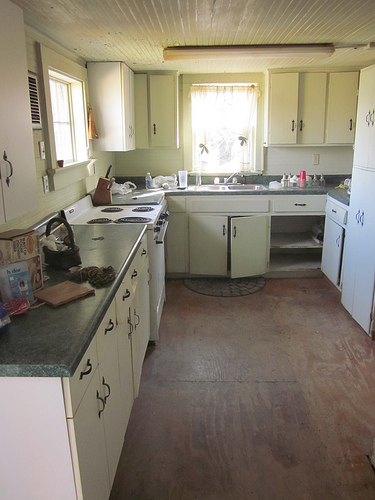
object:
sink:
[190, 172, 267, 192]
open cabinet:
[231, 213, 269, 280]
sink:
[226, 181, 269, 192]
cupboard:
[267, 71, 300, 146]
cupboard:
[297, 72, 326, 144]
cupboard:
[326, 71, 360, 145]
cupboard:
[189, 213, 231, 276]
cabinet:
[68, 346, 126, 498]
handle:
[100, 376, 111, 404]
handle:
[97, 390, 105, 420]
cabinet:
[270, 205, 320, 274]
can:
[1, 295, 29, 317]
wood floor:
[201, 354, 297, 447]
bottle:
[145, 172, 152, 190]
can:
[296, 166, 307, 190]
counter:
[87, 166, 353, 208]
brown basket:
[45, 216, 87, 259]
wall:
[35, 97, 373, 313]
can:
[299, 170, 306, 188]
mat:
[183, 276, 267, 296]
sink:
[185, 182, 267, 193]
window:
[188, 0, 261, 93]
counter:
[9, 315, 88, 355]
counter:
[112, 175, 350, 283]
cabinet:
[161, 212, 343, 279]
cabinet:
[262, 65, 358, 149]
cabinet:
[135, 71, 180, 150]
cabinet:
[83, 59, 134, 153]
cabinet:
[1, 1, 40, 223]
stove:
[61, 195, 170, 347]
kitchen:
[5, 6, 372, 493]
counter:
[200, 183, 346, 197]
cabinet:
[274, 85, 334, 136]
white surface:
[298, 94, 356, 146]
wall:
[98, 137, 183, 178]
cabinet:
[188, 213, 272, 277]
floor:
[111, 278, 374, 498]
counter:
[0, 223, 147, 375]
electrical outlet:
[42, 175, 50, 194]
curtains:
[190, 81, 260, 176]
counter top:
[102, 174, 348, 203]